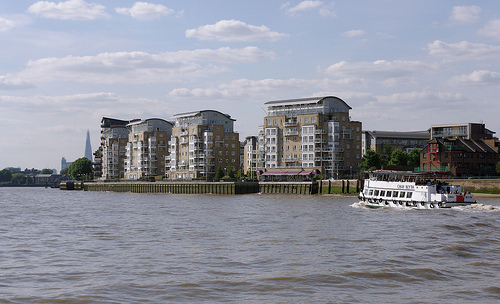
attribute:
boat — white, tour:
[357, 167, 476, 210]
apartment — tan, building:
[247, 97, 362, 187]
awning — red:
[262, 167, 316, 175]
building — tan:
[243, 95, 362, 180]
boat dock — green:
[58, 175, 365, 195]